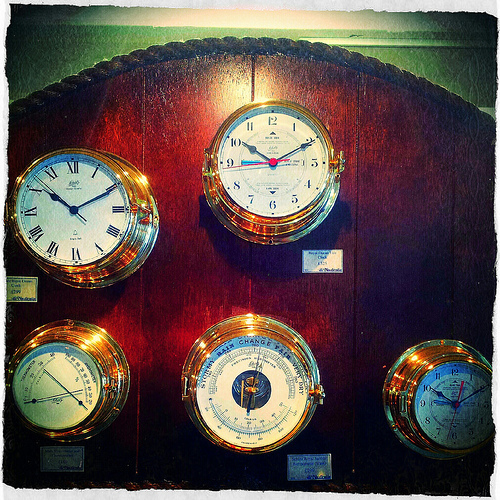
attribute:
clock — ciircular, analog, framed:
[199, 99, 346, 251]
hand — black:
[275, 137, 317, 166]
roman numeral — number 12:
[64, 156, 80, 178]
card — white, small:
[299, 250, 346, 279]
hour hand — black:
[42, 186, 88, 227]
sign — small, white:
[8, 276, 40, 304]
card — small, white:
[283, 451, 336, 483]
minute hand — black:
[79, 189, 115, 223]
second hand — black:
[33, 173, 91, 228]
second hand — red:
[222, 156, 293, 172]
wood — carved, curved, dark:
[8, 37, 496, 489]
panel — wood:
[6, 36, 493, 487]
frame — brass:
[7, 317, 136, 446]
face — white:
[17, 154, 131, 266]